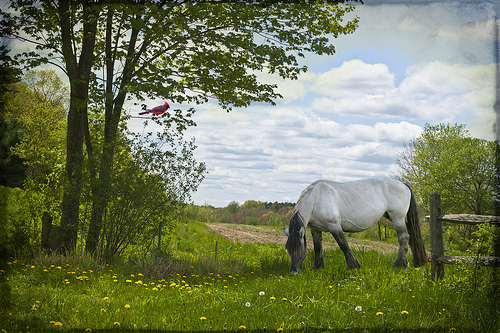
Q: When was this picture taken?
A: Daytime.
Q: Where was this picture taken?
A: A pasture.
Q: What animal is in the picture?
A: A horse.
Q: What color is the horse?
A: Grey.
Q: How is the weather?
A: Sunny.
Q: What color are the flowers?
A: Yellow.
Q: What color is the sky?
A: Blue.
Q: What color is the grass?
A: Green.